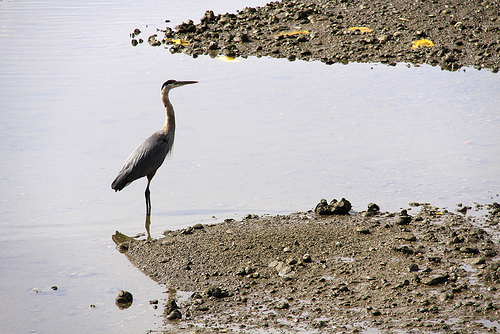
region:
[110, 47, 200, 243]
crane bird standing on dirt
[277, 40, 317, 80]
rock in dirt area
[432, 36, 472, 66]
rock in dirt area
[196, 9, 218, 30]
rock in dirt area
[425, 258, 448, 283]
rock in dirt area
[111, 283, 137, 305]
rock in dirt area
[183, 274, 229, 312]
rock in dirt area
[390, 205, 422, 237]
rock in dirt area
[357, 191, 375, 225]
rock in dirt area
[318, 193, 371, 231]
rock in dirt area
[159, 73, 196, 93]
head of a bird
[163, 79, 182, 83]
forehead of a bird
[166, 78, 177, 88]
eye of a bird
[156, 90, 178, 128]
neck of a bird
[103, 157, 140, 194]
feather of a bird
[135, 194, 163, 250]
leg of a bird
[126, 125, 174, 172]
body of a bird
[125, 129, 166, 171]
wing of a bird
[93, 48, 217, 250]
bird standing near water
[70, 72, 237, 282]
a crane standing in a lake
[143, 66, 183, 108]
the head of a bird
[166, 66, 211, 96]
the beak of a bird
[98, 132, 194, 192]
the body of a bird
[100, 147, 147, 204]
the tail feather of a bird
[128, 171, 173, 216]
the legs of a bird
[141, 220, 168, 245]
the feet of a bird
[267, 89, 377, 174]
the still water of a lake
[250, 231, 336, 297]
a bunch of rocks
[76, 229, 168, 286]
the coast of a lake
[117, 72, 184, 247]
a crane standing in the river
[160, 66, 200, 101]
the head of a crane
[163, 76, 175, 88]
the eye of a crane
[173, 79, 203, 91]
the beak of a crane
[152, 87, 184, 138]
the neck of a crane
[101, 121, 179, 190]
the body of a crane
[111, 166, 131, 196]
the tail feather of a crane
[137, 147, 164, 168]
the wing of a crane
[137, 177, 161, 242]
the legs of a crane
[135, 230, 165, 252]
the feet of a crane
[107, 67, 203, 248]
crane bird in water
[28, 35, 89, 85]
small ripples in water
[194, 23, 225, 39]
several rocks in dirt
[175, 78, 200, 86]
beak of bird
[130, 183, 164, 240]
two legs of crane in water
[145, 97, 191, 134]
neck of crane bird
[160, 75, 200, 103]
head of crane bird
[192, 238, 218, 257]
dirt with small stones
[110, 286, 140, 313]
rock in water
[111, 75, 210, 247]
a bird with long legs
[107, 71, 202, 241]
a bird with a long beak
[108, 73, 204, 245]
a bird standing by the water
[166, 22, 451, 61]
orange spots in the dirt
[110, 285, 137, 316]
a small rock laying in the water by the bird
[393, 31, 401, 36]
A rock on the ground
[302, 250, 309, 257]
A rock on the ground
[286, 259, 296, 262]
A rock on the ground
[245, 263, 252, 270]
A rock on the ground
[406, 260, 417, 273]
A rock on the ground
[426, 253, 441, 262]
A rock on the ground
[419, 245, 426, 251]
A rock on the ground